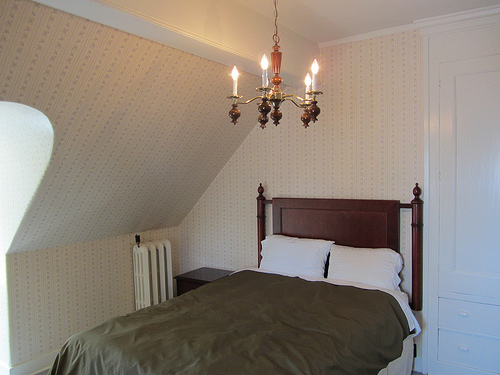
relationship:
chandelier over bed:
[226, 2, 327, 131] [45, 180, 429, 374]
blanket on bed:
[44, 268, 411, 373] [45, 180, 429, 374]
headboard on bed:
[255, 182, 427, 312] [45, 180, 429, 374]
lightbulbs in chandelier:
[228, 52, 323, 85] [226, 2, 327, 131]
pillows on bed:
[256, 230, 407, 291] [45, 180, 429, 374]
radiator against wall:
[131, 236, 175, 310] [4, 225, 179, 366]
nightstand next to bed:
[173, 265, 234, 297] [45, 180, 429, 374]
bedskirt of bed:
[372, 333, 413, 374] [45, 180, 429, 374]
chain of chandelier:
[268, 1, 282, 51] [226, 2, 327, 131]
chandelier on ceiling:
[226, 2, 327, 131] [240, 1, 498, 40]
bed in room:
[45, 180, 429, 374] [2, 2, 496, 372]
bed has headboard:
[45, 180, 429, 374] [255, 182, 427, 312]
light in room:
[226, 2, 327, 131] [2, 2, 496, 372]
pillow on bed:
[258, 231, 335, 282] [45, 180, 429, 374]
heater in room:
[131, 236, 175, 310] [2, 2, 496, 372]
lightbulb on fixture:
[230, 64, 241, 82] [226, 2, 327, 131]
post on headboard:
[407, 181, 426, 312] [255, 182, 427, 312]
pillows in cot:
[256, 230, 407, 291] [45, 180, 429, 374]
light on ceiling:
[226, 2, 327, 131] [240, 1, 498, 40]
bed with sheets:
[45, 180, 429, 374] [44, 268, 411, 373]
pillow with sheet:
[258, 231, 335, 282] [245, 266, 421, 334]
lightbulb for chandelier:
[230, 64, 241, 82] [226, 2, 327, 131]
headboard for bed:
[255, 182, 427, 312] [45, 180, 429, 374]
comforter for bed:
[44, 268, 411, 373] [45, 180, 429, 374]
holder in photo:
[227, 93, 245, 126] [2, 2, 496, 372]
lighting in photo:
[227, 52, 326, 126] [2, 2, 496, 372]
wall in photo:
[4, 225, 179, 366] [2, 2, 496, 372]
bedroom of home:
[2, 2, 496, 372] [31, 57, 498, 372]